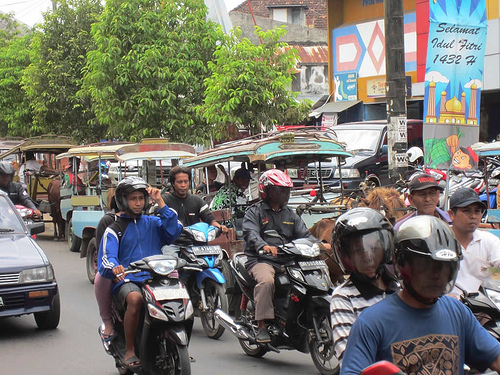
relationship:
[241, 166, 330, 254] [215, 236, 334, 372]
man riding motorcycle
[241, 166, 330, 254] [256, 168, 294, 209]
man wears helmet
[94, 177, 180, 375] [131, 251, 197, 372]
two people riding motorcycle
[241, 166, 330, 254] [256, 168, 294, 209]
man wearing helmet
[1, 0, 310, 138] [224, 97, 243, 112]
trees are full of leaves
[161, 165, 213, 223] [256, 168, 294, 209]
man not wearing helmet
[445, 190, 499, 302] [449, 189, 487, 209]
man wearing ball cap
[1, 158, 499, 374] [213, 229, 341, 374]
people riding motorcycle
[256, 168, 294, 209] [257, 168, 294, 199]
helmet has grapic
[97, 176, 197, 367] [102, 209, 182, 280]
man has on jacket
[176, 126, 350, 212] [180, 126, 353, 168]
bus has a top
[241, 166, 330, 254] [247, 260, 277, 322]
man wearing pants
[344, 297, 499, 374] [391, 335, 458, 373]
shirt has graphic print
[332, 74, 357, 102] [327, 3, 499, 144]
advertising on building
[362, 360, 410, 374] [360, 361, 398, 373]
bike has handle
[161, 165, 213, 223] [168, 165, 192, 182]
man has curly hair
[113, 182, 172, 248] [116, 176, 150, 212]
man wears helmet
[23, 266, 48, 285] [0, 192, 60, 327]
headlight on car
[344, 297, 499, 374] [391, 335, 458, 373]
tee shirt has symbol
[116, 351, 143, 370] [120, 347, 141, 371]
flip flops on feet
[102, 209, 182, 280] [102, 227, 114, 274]
wind breaker has white stripes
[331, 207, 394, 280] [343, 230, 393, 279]
helmet has visor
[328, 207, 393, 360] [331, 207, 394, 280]
woman wears helmet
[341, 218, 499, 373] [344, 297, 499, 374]
man wears blue shirt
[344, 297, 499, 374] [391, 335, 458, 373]
blue shirt has design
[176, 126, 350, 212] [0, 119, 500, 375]
bus on steet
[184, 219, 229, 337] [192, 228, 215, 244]
scooter has headlights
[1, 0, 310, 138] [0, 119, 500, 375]
trees on side of steet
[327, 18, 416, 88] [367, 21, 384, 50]
sign has triangle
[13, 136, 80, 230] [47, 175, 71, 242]
cart driven by horse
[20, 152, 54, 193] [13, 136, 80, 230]
man riding in cart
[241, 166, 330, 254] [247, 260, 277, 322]
man in pants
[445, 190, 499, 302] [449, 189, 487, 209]
man has hat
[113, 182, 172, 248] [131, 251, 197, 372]
man riding motorcycle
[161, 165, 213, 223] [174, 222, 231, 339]
man riding scooter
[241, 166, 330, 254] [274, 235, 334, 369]
man riding motorcycle